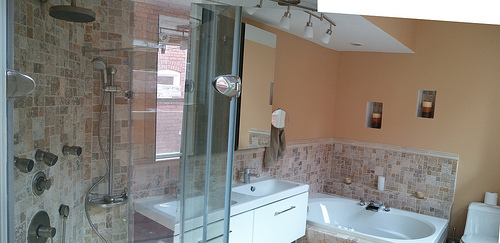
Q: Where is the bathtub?
A: To the right of the sinks.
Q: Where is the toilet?
A: At the end of the tub.